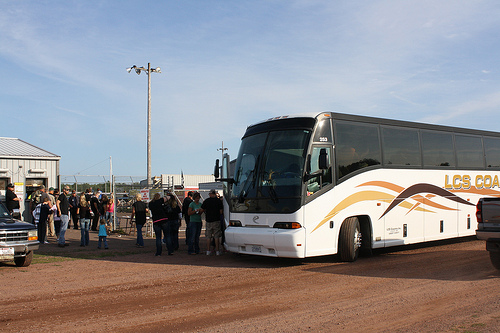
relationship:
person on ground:
[129, 192, 150, 251] [1, 211, 498, 331]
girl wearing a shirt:
[94, 216, 106, 244] [96, 221, 108, 237]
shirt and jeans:
[96, 221, 108, 237] [99, 235, 109, 247]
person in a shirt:
[130, 193, 149, 248] [127, 202, 150, 219]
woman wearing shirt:
[183, 191, 205, 254] [189, 200, 196, 220]